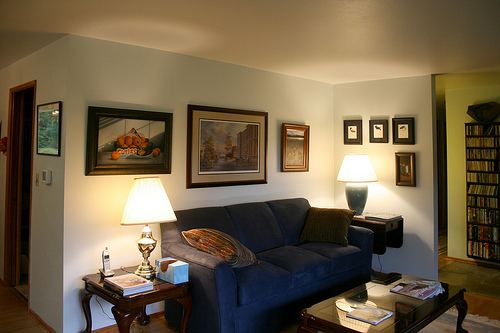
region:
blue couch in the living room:
[158, 186, 383, 331]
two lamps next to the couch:
[126, 140, 392, 322]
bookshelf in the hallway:
[460, 112, 498, 260]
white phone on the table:
[93, 247, 115, 279]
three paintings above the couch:
[88, 91, 313, 187]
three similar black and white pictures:
[337, 111, 422, 148]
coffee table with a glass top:
[307, 272, 471, 332]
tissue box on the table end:
[153, 250, 192, 287]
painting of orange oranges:
[85, 101, 175, 177]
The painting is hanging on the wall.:
[86, 105, 172, 175]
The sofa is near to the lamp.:
[162, 198, 371, 331]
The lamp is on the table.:
[122, 176, 176, 280]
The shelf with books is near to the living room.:
[465, 123, 499, 260]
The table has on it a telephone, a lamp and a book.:
[83, 265, 191, 332]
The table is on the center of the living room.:
[301, 272, 467, 332]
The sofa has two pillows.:
[160, 195, 370, 330]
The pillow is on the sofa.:
[296, 205, 351, 245]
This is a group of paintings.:
[341, 117, 411, 142]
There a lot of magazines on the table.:
[391, 280, 442, 297]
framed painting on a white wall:
[85, 103, 312, 187]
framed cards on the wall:
[341, 117, 415, 144]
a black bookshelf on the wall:
[463, 123, 499, 264]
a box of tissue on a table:
[154, 257, 189, 285]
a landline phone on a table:
[102, 246, 112, 278]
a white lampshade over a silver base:
[122, 174, 176, 277]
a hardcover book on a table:
[103, 274, 154, 299]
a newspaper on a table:
[391, 278, 445, 301]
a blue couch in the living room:
[161, 198, 374, 331]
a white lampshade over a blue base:
[336, 153, 379, 216]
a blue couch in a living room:
[157, 198, 371, 317]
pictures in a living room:
[79, 100, 309, 179]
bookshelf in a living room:
[461, 118, 497, 260]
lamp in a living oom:
[124, 174, 174, 275]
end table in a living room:
[79, 271, 199, 332]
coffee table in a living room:
[310, 272, 468, 328]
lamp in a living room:
[335, 150, 374, 217]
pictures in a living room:
[339, 113, 414, 147]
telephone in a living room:
[97, 246, 114, 278]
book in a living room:
[109, 273, 151, 298]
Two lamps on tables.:
[118, 152, 380, 282]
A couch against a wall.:
[158, 195, 374, 330]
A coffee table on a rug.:
[298, 269, 469, 331]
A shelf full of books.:
[463, 120, 499, 267]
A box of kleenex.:
[153, 255, 189, 285]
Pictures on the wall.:
[34, 100, 418, 190]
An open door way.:
[3, 78, 39, 313]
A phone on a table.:
[98, 245, 113, 276]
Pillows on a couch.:
[179, 204, 356, 269]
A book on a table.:
[102, 271, 154, 296]